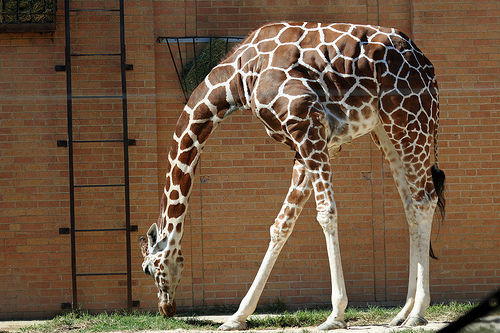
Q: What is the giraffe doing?
A: Bending over.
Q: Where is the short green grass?
A: On the ground.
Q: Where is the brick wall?
A: Behind the giraffe.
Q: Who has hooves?
A: The giraffe.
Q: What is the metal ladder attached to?
A: The wall.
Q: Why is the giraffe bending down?
A: To eat the grass.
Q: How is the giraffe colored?
A: Brown and tan.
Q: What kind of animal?
A: Giraffe.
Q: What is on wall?
A: Ladder.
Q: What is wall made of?
A: Brick.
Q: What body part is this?
A: Legs.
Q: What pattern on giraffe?
A: Spotted.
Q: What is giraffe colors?
A: Brown and white.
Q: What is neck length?
A: Long.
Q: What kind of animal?
A: Giraffe.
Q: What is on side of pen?
A: Ladder.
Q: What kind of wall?
A: Brick.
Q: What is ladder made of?
A: Metal.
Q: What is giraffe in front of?
A: Wall.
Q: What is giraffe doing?
A: Eating.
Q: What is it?
A: Giraffe.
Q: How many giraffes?
A: 1.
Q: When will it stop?
A: Soon.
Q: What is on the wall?
A: Ladder.